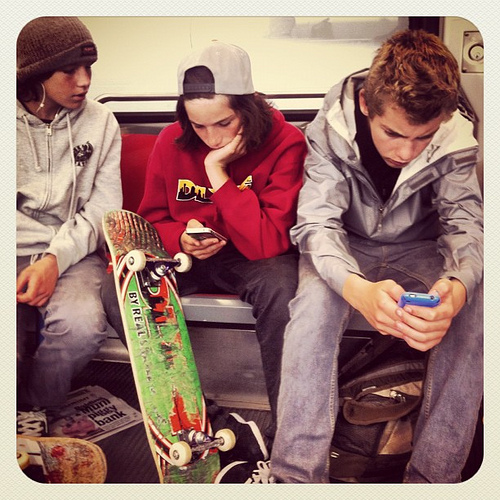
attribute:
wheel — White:
[127, 249, 147, 270]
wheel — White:
[171, 250, 188, 277]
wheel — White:
[212, 430, 234, 451]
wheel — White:
[167, 438, 189, 463]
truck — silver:
[144, 252, 176, 268]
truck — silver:
[188, 430, 223, 456]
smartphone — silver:
[182, 225, 229, 246]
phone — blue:
[385, 274, 465, 358]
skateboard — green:
[98, 207, 239, 484]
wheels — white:
[122, 247, 237, 466]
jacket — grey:
[292, 103, 484, 277]